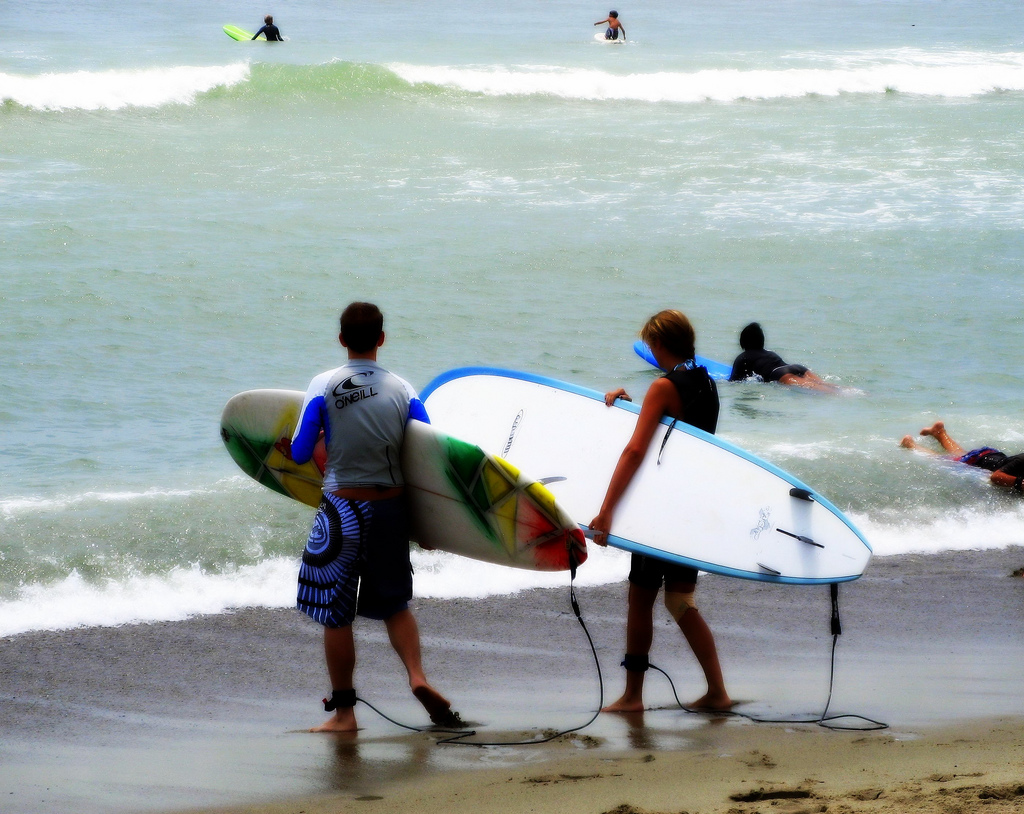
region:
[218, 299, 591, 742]
Young boy holding surfboard.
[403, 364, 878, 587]
Blue and white surfboard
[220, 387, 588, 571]
Green, white, yellow, and red surfboard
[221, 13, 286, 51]
Surfer paddling on a green surfboard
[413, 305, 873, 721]
Surfer in black carrying blue and white board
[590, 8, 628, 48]
Young boy kneeling on surfboard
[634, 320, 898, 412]
Young surfer paddling on blue board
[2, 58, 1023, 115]
Breaking waves away from shore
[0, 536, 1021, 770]
Wet sand at the waters edge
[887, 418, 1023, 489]
Young child riding wave into shore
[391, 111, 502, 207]
a view of water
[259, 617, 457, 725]
legs of the person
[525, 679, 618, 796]
a view of thread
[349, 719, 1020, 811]
A dry sand beach.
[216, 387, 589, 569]
A white surfboard with green, red and yellow on it.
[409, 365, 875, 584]
A white surfboard with blue trim.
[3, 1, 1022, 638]
A blue wavy body of water.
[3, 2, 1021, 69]
A bluer section of water.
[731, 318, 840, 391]
A person with black hair in a black shirt on a blue surfboard.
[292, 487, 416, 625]
Black and blue swimming shorts.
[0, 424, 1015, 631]
A white and grey wave coming to shore.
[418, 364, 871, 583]
A blue trimmed white surfboard.